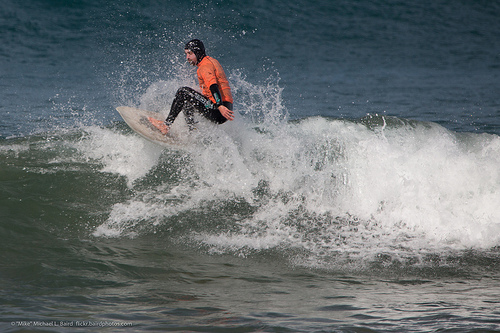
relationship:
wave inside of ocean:
[2, 109, 499, 278] [2, 2, 500, 333]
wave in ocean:
[2, 109, 499, 278] [2, 2, 500, 333]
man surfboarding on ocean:
[144, 38, 237, 140] [2, 2, 500, 333]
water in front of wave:
[1, 245, 499, 333] [2, 109, 499, 278]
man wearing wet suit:
[144, 38, 237, 140] [165, 37, 234, 133]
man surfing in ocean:
[144, 38, 237, 140] [2, 2, 500, 333]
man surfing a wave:
[144, 38, 237, 140] [2, 109, 499, 278]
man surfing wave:
[144, 38, 237, 140] [2, 109, 499, 278]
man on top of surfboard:
[144, 38, 237, 140] [112, 103, 192, 154]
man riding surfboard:
[144, 38, 237, 140] [112, 103, 192, 154]